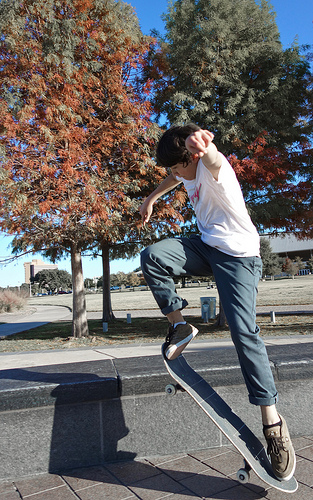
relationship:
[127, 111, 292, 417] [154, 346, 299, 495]
boy on board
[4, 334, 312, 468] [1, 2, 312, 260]
road beside trees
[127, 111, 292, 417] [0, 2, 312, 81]
boy below sky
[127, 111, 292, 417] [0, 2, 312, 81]
boy under sky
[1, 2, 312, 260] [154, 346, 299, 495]
trees beside board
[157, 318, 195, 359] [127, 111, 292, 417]
shoe on boy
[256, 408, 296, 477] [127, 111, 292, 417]
shoe on boy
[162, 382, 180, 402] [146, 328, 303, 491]
wheel on board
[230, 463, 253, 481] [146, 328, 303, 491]
wheel on board